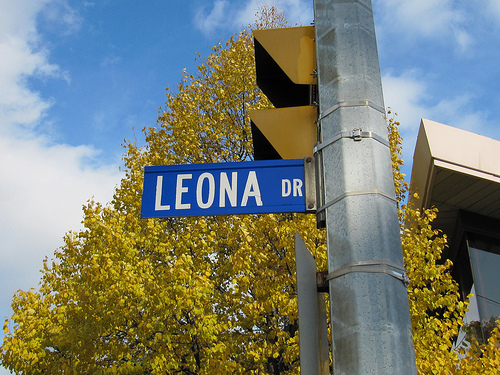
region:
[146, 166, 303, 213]
Street sign saying Leona Dr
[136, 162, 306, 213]
Blue street sign on pole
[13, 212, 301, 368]
tree with yellow leaves behind pole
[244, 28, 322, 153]
street crossing signals above street sign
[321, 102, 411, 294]
steel bands holding signs to pole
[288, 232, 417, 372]
street sign fastened to pole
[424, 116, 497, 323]
tan building with windows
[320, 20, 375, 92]
discolored section on pole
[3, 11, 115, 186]
clear blue sky with clouds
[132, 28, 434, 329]
street sign with crossing signal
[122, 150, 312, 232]
the sign is connected to the pole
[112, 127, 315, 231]
the sign is royal blue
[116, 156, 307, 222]
the letters are white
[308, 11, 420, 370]
the pole is grey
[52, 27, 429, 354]
the tree is yellow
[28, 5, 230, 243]
the sky is partly cloudy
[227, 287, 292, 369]
the branches are dark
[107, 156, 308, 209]
the sign says LEONIA DR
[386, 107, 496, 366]
the building is behind the pole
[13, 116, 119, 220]
the clouds are fluffy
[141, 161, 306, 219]
Street sign on metal pole is blue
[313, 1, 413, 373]
Large metal pole holding signs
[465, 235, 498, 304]
Window on building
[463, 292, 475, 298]
Small yellow leaf on tree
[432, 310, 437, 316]
Small yellow leaf on tree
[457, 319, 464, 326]
Small yellow leaf on tree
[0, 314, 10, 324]
Small yellow leaf on tree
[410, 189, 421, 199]
Small yellow leaf on tree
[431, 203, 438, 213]
Small yellow leaf on tree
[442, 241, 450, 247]
Small yellow leaf on tree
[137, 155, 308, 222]
a blue street sign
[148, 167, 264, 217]
white writing on the sign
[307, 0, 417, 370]
a gray metal sign post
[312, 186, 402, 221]
a gray metal ring on the post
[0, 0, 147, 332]
a white cloud in the sky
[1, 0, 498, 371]
a cloudy blue sky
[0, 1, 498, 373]
a leafy yellow tree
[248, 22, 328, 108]
a yellow and black sign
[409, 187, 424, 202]
a leaf on the tree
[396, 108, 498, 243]
the corner of a building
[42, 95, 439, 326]
a streets sign on a pole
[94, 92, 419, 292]
a street sign on a pole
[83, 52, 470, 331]
a blue sign on a pole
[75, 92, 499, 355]
a sign on a metal pole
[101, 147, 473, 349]
a streets sign on a metal pole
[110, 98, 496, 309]
a blue street sign on pole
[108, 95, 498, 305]
a blue sign on a metal pole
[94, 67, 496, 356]
leona dr street sign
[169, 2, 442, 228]
a traffic light on pole